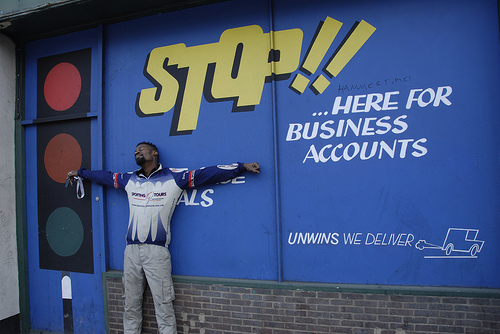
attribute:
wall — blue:
[3, 2, 500, 333]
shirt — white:
[82, 165, 244, 250]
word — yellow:
[126, 26, 367, 140]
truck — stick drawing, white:
[417, 226, 485, 261]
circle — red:
[40, 59, 84, 115]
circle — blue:
[39, 199, 88, 262]